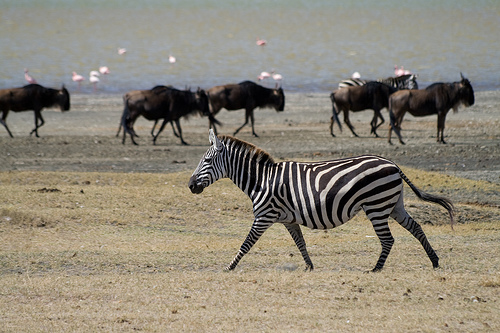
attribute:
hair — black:
[219, 129, 284, 168]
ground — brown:
[13, 234, 498, 329]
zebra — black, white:
[173, 120, 457, 284]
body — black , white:
[253, 153, 402, 229]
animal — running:
[186, 130, 456, 274]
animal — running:
[0, 80, 70, 138]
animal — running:
[388, 70, 475, 138]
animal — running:
[207, 79, 284, 139]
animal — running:
[329, 73, 414, 137]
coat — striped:
[201, 140, 444, 267]